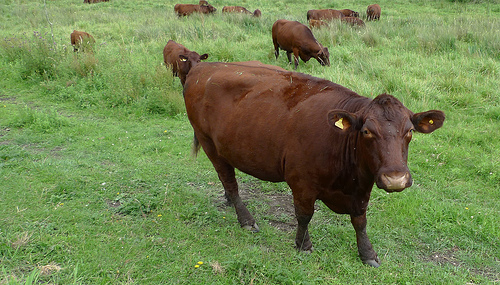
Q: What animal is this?
A: Cow.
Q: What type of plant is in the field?
A: Grass.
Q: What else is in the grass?
A: Dirt.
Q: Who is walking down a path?
A: Cow.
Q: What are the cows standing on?
A: Grass.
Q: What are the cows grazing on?
A: Grass.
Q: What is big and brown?
A: A cow.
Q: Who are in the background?
A: Smaller cows.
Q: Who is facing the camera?
A: A cow.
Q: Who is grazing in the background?
A: Cattle.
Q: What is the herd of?
A: Cattle.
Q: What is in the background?
A: Taller grass.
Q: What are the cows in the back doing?
A: Grazing.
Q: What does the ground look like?
A: Green grass.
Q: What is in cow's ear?
A: Tag.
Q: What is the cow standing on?
A: Dead grass.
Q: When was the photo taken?
A: Daytime.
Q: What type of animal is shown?
A: Cow.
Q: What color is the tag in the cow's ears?
A: Yellow.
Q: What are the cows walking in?
A: Grass.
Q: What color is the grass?
A: Green.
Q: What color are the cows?
A: Brown.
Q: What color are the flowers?
A: Yellow.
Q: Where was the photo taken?
A: Near cow.